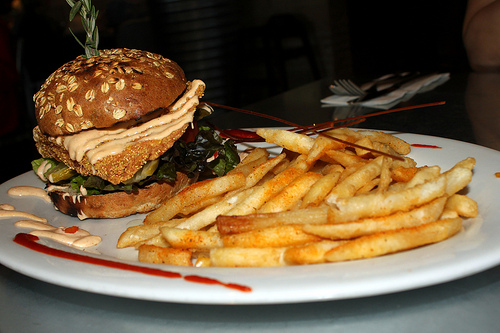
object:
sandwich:
[27, 47, 234, 222]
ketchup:
[9, 228, 252, 295]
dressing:
[10, 217, 105, 251]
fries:
[323, 219, 476, 264]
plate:
[0, 126, 499, 307]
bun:
[29, 47, 189, 139]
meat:
[33, 79, 209, 186]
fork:
[333, 64, 430, 99]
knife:
[346, 73, 434, 106]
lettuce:
[154, 130, 239, 176]